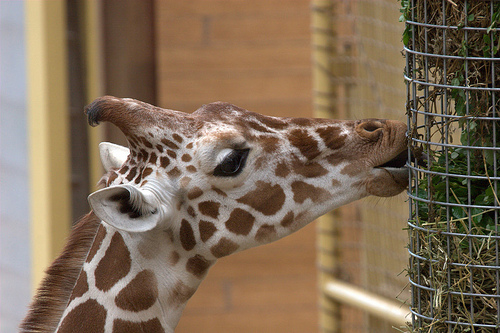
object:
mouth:
[377, 139, 416, 182]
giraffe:
[20, 93, 419, 332]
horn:
[85, 95, 180, 148]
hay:
[413, 0, 499, 328]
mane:
[18, 207, 100, 332]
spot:
[315, 122, 351, 150]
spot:
[284, 127, 324, 163]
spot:
[271, 154, 291, 179]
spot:
[290, 177, 330, 204]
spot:
[280, 211, 298, 230]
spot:
[235, 175, 287, 218]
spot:
[220, 203, 257, 238]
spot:
[195, 200, 225, 222]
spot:
[175, 219, 197, 252]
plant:
[398, 0, 416, 46]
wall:
[151, 0, 366, 332]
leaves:
[446, 203, 487, 225]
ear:
[96, 139, 126, 174]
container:
[401, 0, 500, 332]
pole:
[324, 278, 419, 329]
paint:
[24, 0, 73, 303]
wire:
[461, 1, 479, 332]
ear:
[85, 182, 170, 233]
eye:
[210, 147, 251, 179]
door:
[155, 0, 367, 332]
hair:
[17, 207, 103, 331]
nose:
[348, 111, 393, 141]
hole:
[362, 123, 380, 134]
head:
[71, 97, 409, 256]